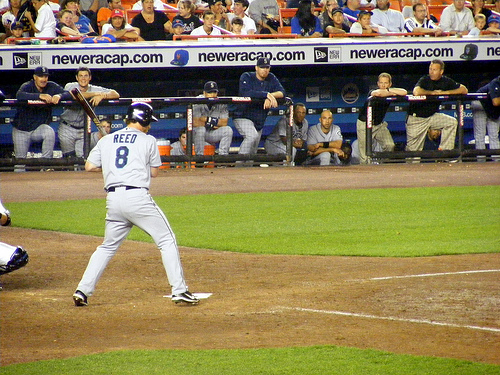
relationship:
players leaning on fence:
[195, 74, 440, 175] [212, 89, 346, 160]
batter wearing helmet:
[73, 102, 201, 306] [124, 94, 170, 126]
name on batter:
[113, 135, 136, 142] [73, 102, 201, 306]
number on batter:
[114, 145, 126, 167] [73, 102, 201, 306]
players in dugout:
[301, 77, 472, 154] [208, 71, 443, 171]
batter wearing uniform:
[73, 102, 201, 306] [55, 132, 205, 319]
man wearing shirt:
[229, 53, 290, 165] [239, 71, 283, 119]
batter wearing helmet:
[73, 102, 201, 306] [121, 95, 159, 127]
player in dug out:
[7, 64, 73, 170] [0, 60, 500, 172]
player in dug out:
[57, 62, 119, 163] [0, 60, 500, 172]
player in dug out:
[183, 80, 234, 158] [0, 60, 500, 172]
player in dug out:
[227, 54, 290, 158] [0, 60, 500, 172]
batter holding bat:
[73, 102, 201, 306] [65, 85, 105, 136]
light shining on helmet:
[129, 108, 146, 123] [120, 97, 163, 127]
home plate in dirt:
[163, 285, 212, 306] [1, 167, 498, 360]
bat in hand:
[70, 87, 105, 134] [95, 120, 115, 136]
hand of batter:
[95, 120, 115, 136] [73, 102, 201, 306]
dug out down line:
[0, 60, 500, 172] [269, 300, 496, 338]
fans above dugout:
[1, 1, 500, 43] [0, 69, 499, 174]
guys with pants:
[6, 63, 122, 162] [6, 125, 89, 166]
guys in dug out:
[6, 63, 122, 162] [2, 62, 489, 167]